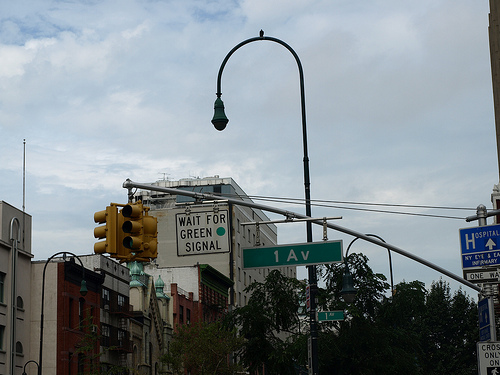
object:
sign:
[241, 240, 344, 268]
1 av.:
[272, 247, 314, 265]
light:
[120, 200, 146, 265]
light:
[92, 201, 119, 255]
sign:
[315, 307, 344, 320]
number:
[321, 309, 341, 321]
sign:
[312, 309, 355, 322]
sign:
[458, 224, 500, 270]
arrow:
[480, 237, 497, 250]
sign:
[176, 212, 230, 250]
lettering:
[179, 213, 230, 249]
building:
[34, 252, 114, 373]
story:
[55, 347, 105, 374]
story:
[57, 288, 100, 339]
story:
[36, 260, 98, 296]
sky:
[2, 0, 498, 294]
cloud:
[6, 32, 147, 91]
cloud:
[43, 150, 282, 193]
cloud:
[344, 171, 467, 227]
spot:
[5, 16, 39, 33]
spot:
[34, 25, 122, 79]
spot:
[10, 37, 34, 50]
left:
[0, 2, 122, 71]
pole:
[208, 28, 331, 369]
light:
[207, 96, 231, 128]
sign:
[462, 267, 500, 286]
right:
[467, 270, 499, 283]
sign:
[470, 340, 498, 373]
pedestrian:
[483, 363, 500, 373]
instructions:
[480, 340, 500, 366]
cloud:
[244, 2, 499, 60]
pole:
[123, 175, 485, 301]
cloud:
[138, 2, 260, 35]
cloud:
[153, 68, 301, 118]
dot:
[214, 225, 228, 242]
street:
[471, 5, 500, 370]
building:
[2, 197, 39, 373]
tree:
[461, 295, 479, 373]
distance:
[247, 276, 482, 373]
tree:
[421, 276, 455, 369]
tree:
[335, 252, 382, 374]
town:
[2, 0, 498, 370]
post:
[450, 200, 499, 338]